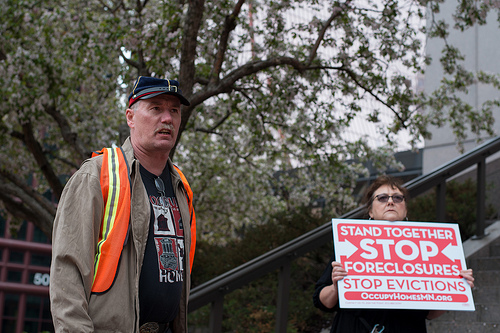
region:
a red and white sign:
[324, 213, 479, 318]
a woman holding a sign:
[320, 179, 478, 330]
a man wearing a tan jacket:
[43, 71, 200, 331]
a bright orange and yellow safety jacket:
[88, 139, 200, 299]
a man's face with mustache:
[121, 91, 185, 158]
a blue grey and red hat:
[125, 71, 189, 106]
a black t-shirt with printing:
[136, 163, 189, 332]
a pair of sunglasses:
[370, 191, 406, 205]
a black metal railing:
[185, 124, 497, 327]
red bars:
[1, 209, 52, 325]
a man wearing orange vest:
[60, 45, 250, 308]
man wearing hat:
[55, 27, 242, 263]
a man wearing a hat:
[47, 41, 229, 328]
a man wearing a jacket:
[37, 47, 237, 328]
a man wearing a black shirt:
[54, 41, 255, 330]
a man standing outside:
[54, 18, 239, 331]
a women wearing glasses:
[304, 122, 499, 329]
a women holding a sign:
[248, 117, 499, 332]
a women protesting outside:
[296, 136, 498, 325]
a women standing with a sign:
[259, 128, 433, 330]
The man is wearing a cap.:
[116, 67, 188, 160]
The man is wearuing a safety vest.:
[40, 66, 213, 331]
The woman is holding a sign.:
[311, 157, 486, 332]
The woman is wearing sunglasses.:
[288, 166, 484, 331]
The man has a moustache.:
[35, 69, 318, 329]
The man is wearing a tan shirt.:
[39, 64, 209, 331]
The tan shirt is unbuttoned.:
[32, 69, 204, 330]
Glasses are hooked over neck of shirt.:
[41, 61, 213, 331]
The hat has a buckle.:
[118, 64, 193, 159]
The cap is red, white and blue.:
[110, 62, 202, 165]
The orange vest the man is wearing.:
[94, 145, 203, 285]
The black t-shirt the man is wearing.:
[137, 165, 200, 312]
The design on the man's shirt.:
[150, 185, 194, 300]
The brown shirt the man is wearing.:
[65, 152, 200, 324]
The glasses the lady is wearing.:
[374, 189, 406, 209]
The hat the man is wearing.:
[129, 74, 197, 108]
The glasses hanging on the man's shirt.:
[153, 174, 171, 209]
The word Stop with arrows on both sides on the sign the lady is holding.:
[358, 230, 433, 260]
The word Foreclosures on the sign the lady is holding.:
[345, 257, 456, 272]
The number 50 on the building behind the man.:
[29, 265, 51, 292]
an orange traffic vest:
[60, 120, 222, 307]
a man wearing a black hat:
[90, 57, 207, 165]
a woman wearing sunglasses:
[357, 169, 422, 228]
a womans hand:
[302, 247, 356, 319]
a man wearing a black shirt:
[100, 145, 242, 328]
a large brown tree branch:
[187, 4, 402, 161]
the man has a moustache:
[139, 115, 182, 151]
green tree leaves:
[212, 99, 319, 213]